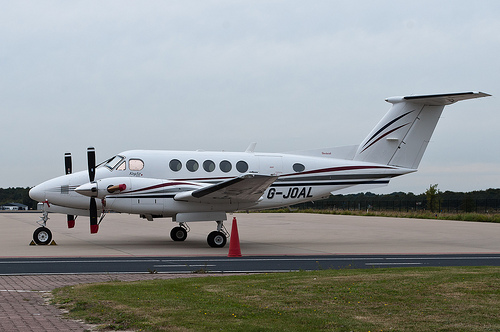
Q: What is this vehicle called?
A: Airplane.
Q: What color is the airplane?
A: White.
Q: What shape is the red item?
A: Cone.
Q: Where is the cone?
A: In front of the plane.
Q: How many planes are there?
A: One.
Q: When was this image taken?
A: Daytime.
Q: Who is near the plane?
A: No one.